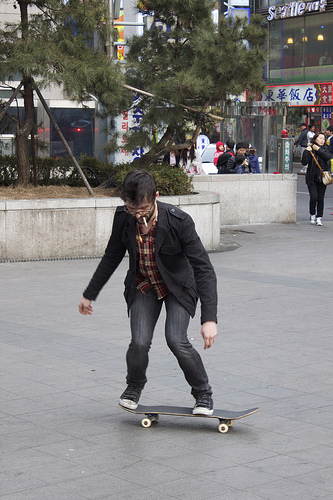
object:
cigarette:
[143, 217, 149, 228]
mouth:
[136, 216, 146, 222]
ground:
[258, 425, 322, 489]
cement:
[22, 388, 106, 446]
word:
[289, 88, 301, 102]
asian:
[301, 132, 332, 226]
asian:
[235, 154, 253, 174]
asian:
[325, 124, 332, 176]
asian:
[214, 141, 225, 169]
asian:
[307, 123, 316, 143]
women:
[301, 132, 332, 227]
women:
[179, 133, 206, 175]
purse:
[322, 170, 333, 185]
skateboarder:
[80, 173, 260, 433]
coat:
[213, 141, 225, 169]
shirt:
[133, 204, 172, 302]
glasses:
[123, 201, 153, 216]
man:
[78, 170, 218, 417]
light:
[77, 127, 81, 131]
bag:
[322, 171, 333, 185]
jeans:
[125, 283, 212, 391]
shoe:
[192, 395, 214, 416]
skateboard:
[118, 398, 259, 435]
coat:
[82, 200, 217, 325]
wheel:
[142, 418, 151, 428]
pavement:
[29, 438, 329, 496]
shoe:
[119, 383, 142, 410]